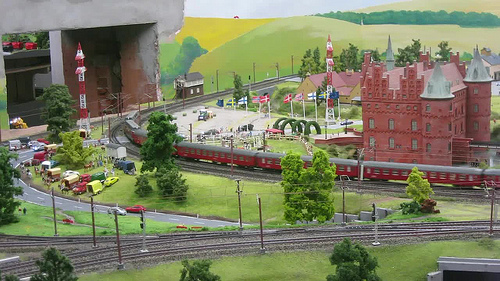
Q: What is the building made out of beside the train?
A: The building is brick.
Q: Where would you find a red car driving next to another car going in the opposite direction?
A: On the street.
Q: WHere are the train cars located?
A: On the tracks next to the red brick building.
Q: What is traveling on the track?
A: A red train.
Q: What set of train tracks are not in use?
A: The tracks at the bottom.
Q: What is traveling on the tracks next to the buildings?
A: The train.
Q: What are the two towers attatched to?
A: The big brick building.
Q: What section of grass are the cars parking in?
A: Near the trees next to the train tracks.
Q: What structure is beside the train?
A: A castle.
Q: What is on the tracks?
A: A train.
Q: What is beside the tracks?
A: A road.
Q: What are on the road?
A: Cars.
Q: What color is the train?
A: Red.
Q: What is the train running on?
A: Tracks.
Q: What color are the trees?
A: Green.